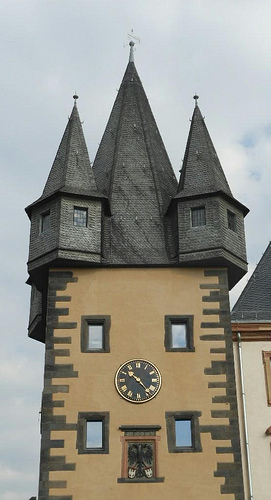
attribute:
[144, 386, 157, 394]
roman numeral — roman 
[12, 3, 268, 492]
picture — outdoors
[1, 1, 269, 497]
sky — Light blue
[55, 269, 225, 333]
building — brick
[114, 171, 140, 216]
tile — Dark grey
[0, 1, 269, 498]
skys — clear 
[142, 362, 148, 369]
roman numeral — roman 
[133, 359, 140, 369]
roman numeral — roman 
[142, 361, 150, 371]
roman numeral — roman 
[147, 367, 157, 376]
roman numeral — roman 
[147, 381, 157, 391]
roman numeral — roman 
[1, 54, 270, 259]
building — old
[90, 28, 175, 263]
spire — tallest 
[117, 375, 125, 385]
numeral — roman 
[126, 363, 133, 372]
numeral — roman 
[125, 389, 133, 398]
numeral — roman 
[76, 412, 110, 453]
frame — Black 